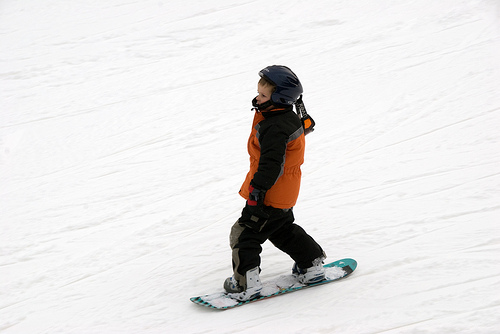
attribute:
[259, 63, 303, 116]
helmet — black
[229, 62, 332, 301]
child — snowboarding, young, white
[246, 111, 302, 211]
coat — orange, black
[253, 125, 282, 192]
sleeve — black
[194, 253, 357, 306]
snowboard — blue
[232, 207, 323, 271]
pants — black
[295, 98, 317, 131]
goggles — hanging, ski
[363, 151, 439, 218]
tracks — ski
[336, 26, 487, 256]
snow — white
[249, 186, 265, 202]
glove — black, winter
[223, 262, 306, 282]
boots — clipped in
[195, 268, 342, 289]
board — white, blue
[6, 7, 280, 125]
time — day